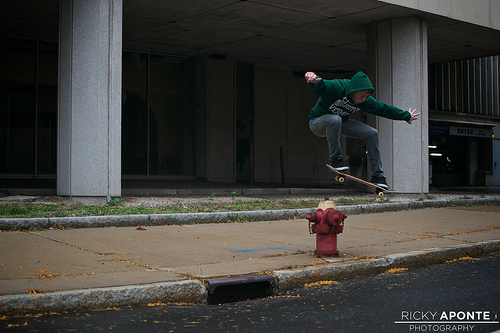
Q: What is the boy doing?
A: Skateboarding.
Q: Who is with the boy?
A: No one.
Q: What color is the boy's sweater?
A: Green.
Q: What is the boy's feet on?
A: Skateboard.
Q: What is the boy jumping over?
A: Fire hydrant.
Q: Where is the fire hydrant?
A: Sidewalk.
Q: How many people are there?
A: One.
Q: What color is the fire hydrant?
A: Red.